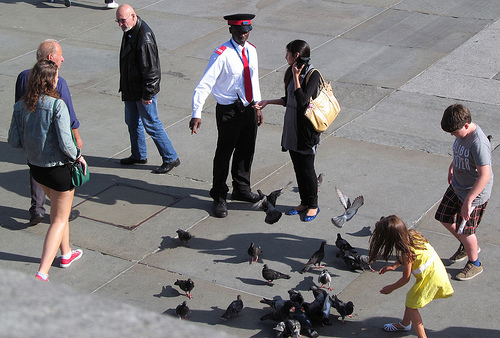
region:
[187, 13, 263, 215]
a man wearing a uniform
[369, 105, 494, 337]
children playing with birds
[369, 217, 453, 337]
girl in a yellow sundress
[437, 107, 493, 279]
boy wearing brown shorts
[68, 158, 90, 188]
a green female clutch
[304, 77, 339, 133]
large brown pocket book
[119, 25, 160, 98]
a leather jacket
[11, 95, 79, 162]
a light blue jean jacket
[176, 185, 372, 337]
a flock of birds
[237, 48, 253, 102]
a red tie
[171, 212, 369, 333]
several birds on the cement pavement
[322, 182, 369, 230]
a bird flying away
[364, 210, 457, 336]
a girl wearing a yellow dress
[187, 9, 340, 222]
a man and woman standing by each other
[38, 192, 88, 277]
the legs of a person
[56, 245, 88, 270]
a red tennis shoe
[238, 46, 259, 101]
a red tie on a man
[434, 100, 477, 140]
a head of a boy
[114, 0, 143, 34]
the head of a man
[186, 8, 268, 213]
a man in a uniform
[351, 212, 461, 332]
A young girl feeding pigeons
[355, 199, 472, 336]
A young girl in a yellow dress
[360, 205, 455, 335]
A young girl with white sandals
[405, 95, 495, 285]
A boy in a grey shirt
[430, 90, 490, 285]
A boy standing next to a group of pigeons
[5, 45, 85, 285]
A woman with a green purse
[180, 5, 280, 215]
A man with a red tie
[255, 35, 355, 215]
A woman with blue sandals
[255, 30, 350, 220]
A woman with a gold purse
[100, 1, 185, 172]
A man in a leather jacket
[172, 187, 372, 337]
pigeons grouped together on paved cement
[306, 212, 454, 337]
young girl bending towards pigeons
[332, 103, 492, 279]
boy looking down towards birds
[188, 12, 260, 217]
man in uniform pointing down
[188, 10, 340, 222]
young woman reaching towards man in uniform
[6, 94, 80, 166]
woman wearing a blue denim jacket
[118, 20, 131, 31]
man has white facial hair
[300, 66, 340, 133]
woman carrying a large light brown bag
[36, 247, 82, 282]
woman is wearing pink and white shoes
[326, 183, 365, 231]
a pigeon extending its wings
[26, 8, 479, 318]
The people are walking around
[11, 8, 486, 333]
People are in the city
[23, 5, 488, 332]
A child is feeding some pigeons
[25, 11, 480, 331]
The pigeons are getting some food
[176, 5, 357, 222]
A woman is talking to a man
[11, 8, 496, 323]
The people are up in daytime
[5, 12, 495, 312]
The people are enjoying the city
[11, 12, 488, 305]
People are enjoying their day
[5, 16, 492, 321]
The people are out in the sunshine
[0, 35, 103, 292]
A man and a woman are walking around